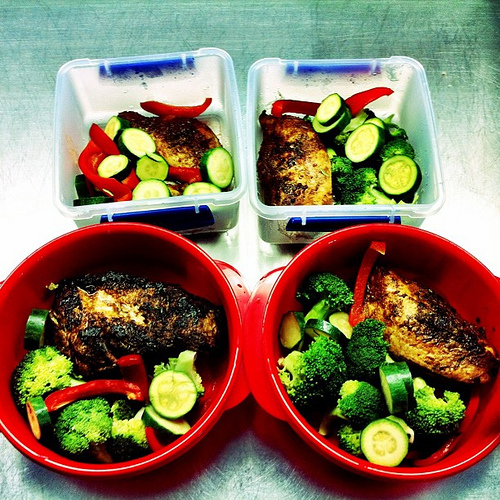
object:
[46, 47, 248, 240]
container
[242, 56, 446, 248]
container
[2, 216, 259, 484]
bowl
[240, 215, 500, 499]
bowl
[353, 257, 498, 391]
meat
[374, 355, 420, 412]
cucumber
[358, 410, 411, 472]
cucumber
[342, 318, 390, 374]
broccoli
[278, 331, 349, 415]
broccoli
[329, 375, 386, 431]
broccoli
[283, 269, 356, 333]
broccoli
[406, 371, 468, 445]
broccoli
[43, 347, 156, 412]
peppers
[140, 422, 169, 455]
peppers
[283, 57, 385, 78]
handle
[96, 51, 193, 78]
handle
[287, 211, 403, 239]
handle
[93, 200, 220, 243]
handle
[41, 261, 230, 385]
meat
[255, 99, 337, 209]
meat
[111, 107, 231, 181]
meat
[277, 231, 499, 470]
dinner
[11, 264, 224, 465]
dinner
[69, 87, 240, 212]
meal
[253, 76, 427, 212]
meal